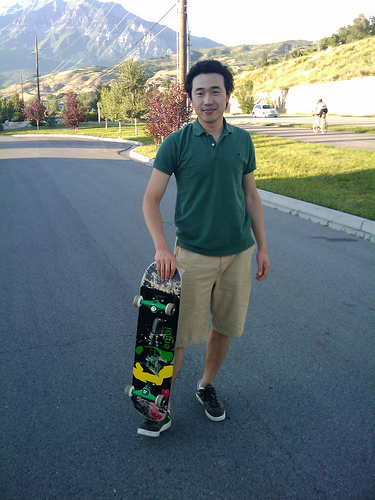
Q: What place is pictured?
A: It is a road.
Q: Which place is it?
A: It is a road.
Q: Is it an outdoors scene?
A: Yes, it is outdoors.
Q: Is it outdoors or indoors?
A: It is outdoors.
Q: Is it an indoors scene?
A: No, it is outdoors.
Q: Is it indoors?
A: No, it is outdoors.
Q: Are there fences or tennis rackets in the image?
A: No, there are no tennis rackets or fences.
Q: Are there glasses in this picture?
A: No, there are no glasses.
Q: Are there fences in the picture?
A: No, there are no fences.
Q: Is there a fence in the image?
A: No, there are no fences.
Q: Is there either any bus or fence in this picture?
A: No, there are no fences or buses.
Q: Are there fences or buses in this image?
A: No, there are no fences or buses.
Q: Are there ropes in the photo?
A: No, there are no ropes.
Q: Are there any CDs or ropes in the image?
A: No, there are no ropes or cds.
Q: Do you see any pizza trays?
A: No, there are no pizza trays.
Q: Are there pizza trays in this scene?
A: No, there are no pizza trays.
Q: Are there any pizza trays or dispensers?
A: No, there are no pizza trays or dispensers.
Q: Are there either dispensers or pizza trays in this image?
A: No, there are no pizza trays or dispensers.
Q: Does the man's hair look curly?
A: Yes, the hair is curly.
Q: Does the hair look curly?
A: Yes, the hair is curly.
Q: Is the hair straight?
A: No, the hair is curly.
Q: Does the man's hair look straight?
A: No, the hair is curly.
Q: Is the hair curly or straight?
A: The hair is curly.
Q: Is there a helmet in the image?
A: No, there are no helmets.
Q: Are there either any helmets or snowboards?
A: No, there are no helmets or snowboards.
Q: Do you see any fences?
A: No, there are no fences.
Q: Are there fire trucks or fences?
A: No, there are no fences or fire trucks.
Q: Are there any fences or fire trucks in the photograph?
A: No, there are no fences or fire trucks.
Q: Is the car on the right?
A: Yes, the car is on the right of the image.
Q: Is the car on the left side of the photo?
A: No, the car is on the right of the image.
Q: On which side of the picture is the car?
A: The car is on the right of the image.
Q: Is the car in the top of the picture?
A: Yes, the car is in the top of the image.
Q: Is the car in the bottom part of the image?
A: No, the car is in the top of the image.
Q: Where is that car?
A: The car is on the road.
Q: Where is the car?
A: The car is on the road.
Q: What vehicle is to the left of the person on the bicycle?
A: The vehicle is a car.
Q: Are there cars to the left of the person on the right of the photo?
A: Yes, there is a car to the left of the person.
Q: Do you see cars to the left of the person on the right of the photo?
A: Yes, there is a car to the left of the person.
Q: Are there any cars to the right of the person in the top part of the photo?
A: No, the car is to the left of the person.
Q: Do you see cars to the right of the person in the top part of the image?
A: No, the car is to the left of the person.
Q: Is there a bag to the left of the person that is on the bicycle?
A: No, there is a car to the left of the person.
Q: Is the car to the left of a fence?
A: No, the car is to the left of a person.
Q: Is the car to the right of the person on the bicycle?
A: No, the car is to the left of the person.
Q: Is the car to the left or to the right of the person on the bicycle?
A: The car is to the left of the person.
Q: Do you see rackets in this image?
A: No, there are no rackets.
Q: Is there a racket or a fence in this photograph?
A: No, there are no rackets or fences.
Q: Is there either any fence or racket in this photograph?
A: No, there are no rackets or fences.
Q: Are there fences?
A: No, there are no fences.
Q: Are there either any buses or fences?
A: No, there are no fences or buses.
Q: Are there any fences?
A: No, there are no fences.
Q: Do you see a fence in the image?
A: No, there are no fences.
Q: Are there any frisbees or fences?
A: No, there are no fences or frisbees.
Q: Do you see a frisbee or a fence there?
A: No, there are no fences or frisbees.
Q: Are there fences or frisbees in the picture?
A: No, there are no fences or frisbees.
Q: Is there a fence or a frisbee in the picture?
A: No, there are no fences or frisbees.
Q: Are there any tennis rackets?
A: No, there are no tennis rackets.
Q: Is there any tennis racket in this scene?
A: No, there are no rackets.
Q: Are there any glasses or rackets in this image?
A: No, there are no rackets or glasses.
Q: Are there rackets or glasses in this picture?
A: No, there are no rackets or glasses.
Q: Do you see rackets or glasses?
A: No, there are no rackets or glasses.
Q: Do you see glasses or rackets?
A: No, there are no rackets or glasses.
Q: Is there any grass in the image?
A: Yes, there is grass.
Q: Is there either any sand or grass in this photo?
A: Yes, there is grass.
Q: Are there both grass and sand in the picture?
A: No, there is grass but no sand.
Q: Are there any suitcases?
A: No, there are no suitcases.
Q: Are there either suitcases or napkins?
A: No, there are no suitcases or napkins.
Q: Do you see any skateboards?
A: Yes, there is a skateboard.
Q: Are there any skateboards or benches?
A: Yes, there is a skateboard.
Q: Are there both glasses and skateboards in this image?
A: No, there is a skateboard but no glasses.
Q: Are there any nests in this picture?
A: No, there are no nests.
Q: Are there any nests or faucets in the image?
A: No, there are no nests or faucets.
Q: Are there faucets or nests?
A: No, there are no nests or faucets.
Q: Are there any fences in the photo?
A: No, there are no fences.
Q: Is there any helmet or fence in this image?
A: No, there are no fences or helmets.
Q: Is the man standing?
A: Yes, the man is standing.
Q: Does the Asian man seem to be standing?
A: Yes, the man is standing.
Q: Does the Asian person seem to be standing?
A: Yes, the man is standing.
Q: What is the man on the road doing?
A: The man is standing.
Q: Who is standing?
A: The man is standing.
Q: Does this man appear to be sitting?
A: No, the man is standing.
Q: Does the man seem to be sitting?
A: No, the man is standing.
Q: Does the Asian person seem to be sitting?
A: No, the man is standing.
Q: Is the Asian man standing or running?
A: The man is standing.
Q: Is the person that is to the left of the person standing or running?
A: The man is standing.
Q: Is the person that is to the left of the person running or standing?
A: The man is standing.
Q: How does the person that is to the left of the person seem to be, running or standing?
A: The man is standing.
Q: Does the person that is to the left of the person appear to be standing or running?
A: The man is standing.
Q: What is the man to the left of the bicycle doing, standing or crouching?
A: The man is standing.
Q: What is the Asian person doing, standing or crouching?
A: The man is standing.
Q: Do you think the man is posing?
A: Yes, the man is posing.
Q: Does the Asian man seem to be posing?
A: Yes, the man is posing.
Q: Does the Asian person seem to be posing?
A: Yes, the man is posing.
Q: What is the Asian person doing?
A: The man is posing.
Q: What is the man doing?
A: The man is posing.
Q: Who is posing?
A: The man is posing.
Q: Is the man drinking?
A: No, the man is posing.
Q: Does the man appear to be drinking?
A: No, the man is posing.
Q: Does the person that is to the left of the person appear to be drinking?
A: No, the man is posing.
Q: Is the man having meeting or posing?
A: The man is posing.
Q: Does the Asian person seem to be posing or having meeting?
A: The man is posing.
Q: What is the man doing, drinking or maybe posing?
A: The man is posing.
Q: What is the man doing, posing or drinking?
A: The man is posing.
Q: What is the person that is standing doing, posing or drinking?
A: The man is posing.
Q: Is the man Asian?
A: Yes, the man is asian.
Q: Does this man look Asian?
A: Yes, the man is asian.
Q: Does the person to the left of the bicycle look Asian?
A: Yes, the man is asian.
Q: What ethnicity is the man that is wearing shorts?
A: The man is asian.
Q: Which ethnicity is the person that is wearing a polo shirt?
A: The man is asian.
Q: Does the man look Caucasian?
A: No, the man is asian.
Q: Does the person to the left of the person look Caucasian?
A: No, the man is asian.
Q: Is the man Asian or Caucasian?
A: The man is asian.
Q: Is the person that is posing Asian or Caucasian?
A: The man is asian.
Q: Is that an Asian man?
A: Yes, that is an Asian man.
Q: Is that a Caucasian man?
A: No, that is an Asian man.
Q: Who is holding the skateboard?
A: The man is holding the skateboard.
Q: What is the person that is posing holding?
A: The man is holding the skateboard.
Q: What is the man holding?
A: The man is holding the skateboard.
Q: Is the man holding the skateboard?
A: Yes, the man is holding the skateboard.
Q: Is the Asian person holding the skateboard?
A: Yes, the man is holding the skateboard.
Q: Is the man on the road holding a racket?
A: No, the man is holding the skateboard.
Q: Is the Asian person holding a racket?
A: No, the man is holding the skateboard.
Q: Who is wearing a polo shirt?
A: The man is wearing a polo shirt.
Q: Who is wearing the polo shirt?
A: The man is wearing a polo shirt.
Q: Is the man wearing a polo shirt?
A: Yes, the man is wearing a polo shirt.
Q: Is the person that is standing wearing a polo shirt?
A: Yes, the man is wearing a polo shirt.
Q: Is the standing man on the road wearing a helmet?
A: No, the man is wearing a polo shirt.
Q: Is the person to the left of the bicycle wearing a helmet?
A: No, the man is wearing a polo shirt.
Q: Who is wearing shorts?
A: The man is wearing shorts.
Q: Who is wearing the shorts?
A: The man is wearing shorts.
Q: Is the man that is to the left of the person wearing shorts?
A: Yes, the man is wearing shorts.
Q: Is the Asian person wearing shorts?
A: Yes, the man is wearing shorts.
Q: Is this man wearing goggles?
A: No, the man is wearing shorts.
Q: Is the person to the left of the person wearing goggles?
A: No, the man is wearing shorts.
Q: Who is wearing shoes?
A: The man is wearing shoes.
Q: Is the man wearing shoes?
A: Yes, the man is wearing shoes.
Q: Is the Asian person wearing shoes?
A: Yes, the man is wearing shoes.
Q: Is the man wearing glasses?
A: No, the man is wearing shoes.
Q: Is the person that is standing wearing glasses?
A: No, the man is wearing shoes.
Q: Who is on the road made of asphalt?
A: The man is on the road.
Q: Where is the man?
A: The man is on the road.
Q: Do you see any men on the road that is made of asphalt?
A: Yes, there is a man on the road.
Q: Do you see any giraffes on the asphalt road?
A: No, there is a man on the road.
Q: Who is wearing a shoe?
A: The man is wearing a shoe.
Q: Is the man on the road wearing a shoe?
A: Yes, the man is wearing a shoe.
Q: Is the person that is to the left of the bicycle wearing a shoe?
A: Yes, the man is wearing a shoe.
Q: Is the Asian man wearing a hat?
A: No, the man is wearing a shoe.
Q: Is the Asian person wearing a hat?
A: No, the man is wearing a shoe.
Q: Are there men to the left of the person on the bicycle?
A: Yes, there is a man to the left of the person.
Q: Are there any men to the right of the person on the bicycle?
A: No, the man is to the left of the person.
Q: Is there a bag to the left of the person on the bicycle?
A: No, there is a man to the left of the person.